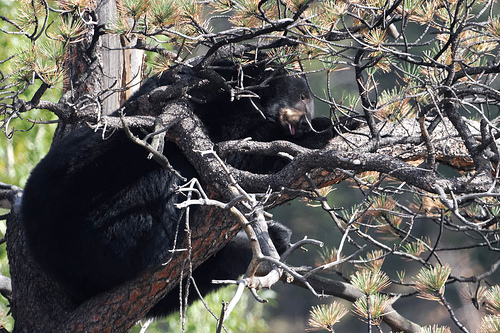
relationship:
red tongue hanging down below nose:
[288, 125, 300, 137] [300, 118, 309, 126]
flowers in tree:
[306, 202, 418, 319] [41, 11, 493, 304]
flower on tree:
[308, 301, 350, 331] [2, 1, 499, 330]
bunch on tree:
[311, 187, 402, 275] [2, 1, 499, 330]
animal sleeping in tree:
[20, 44, 366, 320] [2, 1, 499, 330]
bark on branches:
[171, 100, 488, 272] [195, 150, 452, 291]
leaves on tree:
[14, 0, 46, 28] [2, 1, 499, 330]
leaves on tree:
[362, 247, 386, 269] [2, 1, 499, 330]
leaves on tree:
[413, 263, 450, 298] [2, 1, 499, 330]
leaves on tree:
[375, 85, 409, 118] [2, 1, 499, 330]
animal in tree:
[20, 44, 366, 320] [404, 50, 473, 158]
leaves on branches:
[263, 43, 303, 70] [141, 49, 439, 260]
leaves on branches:
[359, 30, 393, 71] [141, 49, 439, 260]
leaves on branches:
[348, 193, 395, 228] [141, 49, 439, 260]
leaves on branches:
[148, 53, 170, 77] [141, 49, 439, 260]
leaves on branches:
[375, 88, 405, 117] [141, 49, 439, 260]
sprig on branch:
[424, 206, 445, 261] [223, 148, 436, 198]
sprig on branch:
[305, 280, 332, 299] [223, 148, 436, 198]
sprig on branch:
[345, 217, 412, 263] [223, 148, 436, 198]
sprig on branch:
[300, 242, 367, 282] [216, 131, 431, 170]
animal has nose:
[20, 44, 366, 320] [298, 106, 310, 128]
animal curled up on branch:
[20, 44, 366, 320] [85, 119, 496, 330]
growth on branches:
[305, 299, 350, 331] [361, 293, 371, 331]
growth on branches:
[0, 1, 472, 329] [361, 293, 371, 331]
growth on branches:
[0, 1, 472, 329] [327, 323, 334, 330]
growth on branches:
[354, 292, 394, 324] [375, 320, 381, 330]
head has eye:
[206, 35, 354, 185] [292, 82, 314, 101]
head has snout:
[206, 35, 354, 185] [279, 99, 321, 130]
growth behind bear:
[0, 1, 268, 329] [31, 47, 418, 331]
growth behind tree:
[0, 1, 268, 329] [2, 1, 499, 330]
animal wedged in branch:
[20, 44, 366, 320] [3, 113, 499, 325]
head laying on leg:
[235, 62, 312, 137] [240, 110, 368, 164]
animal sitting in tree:
[6, 44, 365, 332] [2, 1, 499, 330]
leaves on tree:
[15, 7, 498, 328] [2, 1, 499, 330]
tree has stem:
[2, 1, 499, 330] [65, 10, 144, 121]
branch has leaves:
[44, 115, 491, 329] [15, 7, 498, 328]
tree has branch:
[2, 1, 499, 330] [44, 115, 491, 329]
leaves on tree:
[347, 271, 392, 294] [2, 1, 499, 330]